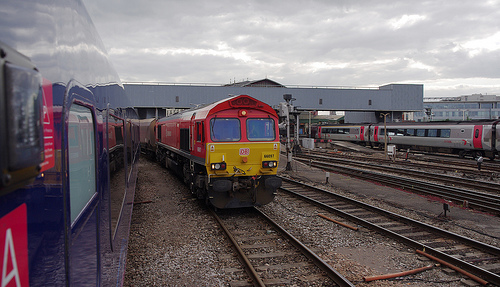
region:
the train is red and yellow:
[146, 77, 306, 256]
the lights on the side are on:
[173, 152, 284, 184]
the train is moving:
[142, 62, 314, 279]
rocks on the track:
[193, 216, 319, 282]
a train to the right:
[270, 87, 488, 190]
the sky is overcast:
[83, 4, 475, 103]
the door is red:
[460, 107, 491, 159]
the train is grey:
[275, 102, 492, 158]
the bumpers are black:
[195, 171, 292, 208]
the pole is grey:
[259, 81, 306, 178]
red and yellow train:
[146, 100, 279, 206]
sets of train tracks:
[204, 155, 478, 264]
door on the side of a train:
[54, 72, 114, 285]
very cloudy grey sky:
[117, 7, 470, 83]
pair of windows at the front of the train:
[206, 112, 279, 142]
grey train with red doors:
[317, 110, 492, 155]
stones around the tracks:
[146, 202, 340, 284]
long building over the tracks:
[134, 75, 428, 120]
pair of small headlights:
[208, 155, 280, 168]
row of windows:
[379, 125, 449, 139]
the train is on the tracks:
[143, 105, 280, 207]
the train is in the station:
[134, 95, 284, 204]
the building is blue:
[117, 81, 422, 128]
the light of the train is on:
[240, 109, 245, 117]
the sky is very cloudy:
[70, 3, 499, 92]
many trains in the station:
[0, 0, 498, 285]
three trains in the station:
[1, 0, 497, 284]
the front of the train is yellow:
[141, 96, 281, 208]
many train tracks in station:
[211, 143, 498, 283]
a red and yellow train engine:
[158, 95, 280, 217]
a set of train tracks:
[212, 200, 352, 285]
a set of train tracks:
[278, 174, 498, 284]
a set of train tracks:
[295, 155, 499, 219]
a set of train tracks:
[311, 147, 497, 179]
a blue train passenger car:
[1, 0, 139, 284]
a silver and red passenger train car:
[313, 121, 368, 143]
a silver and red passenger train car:
[369, 120, 495, 150]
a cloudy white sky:
[80, 1, 499, 94]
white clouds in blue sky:
[12, 5, 81, 34]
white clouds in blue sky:
[93, 13, 152, 45]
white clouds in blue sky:
[143, 44, 173, 72]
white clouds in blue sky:
[169, 8, 221, 38]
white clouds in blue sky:
[197, 32, 249, 72]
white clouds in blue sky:
[251, 39, 292, 68]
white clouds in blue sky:
[274, 11, 314, 40]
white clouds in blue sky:
[376, 2, 436, 41]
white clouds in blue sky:
[320, 38, 375, 71]